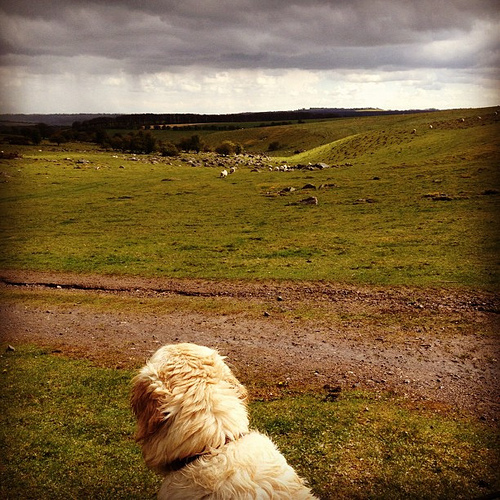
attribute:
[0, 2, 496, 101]
clouds — dark, grey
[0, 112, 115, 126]
tree line — grey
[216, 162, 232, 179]
animal — white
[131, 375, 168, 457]
ears — brown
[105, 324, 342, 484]
dog — blonde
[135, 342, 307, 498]
fur — brown, light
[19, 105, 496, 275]
hills — grassy, green, rolling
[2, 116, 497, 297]
rolling hills — green, grassy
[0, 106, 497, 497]
grass — soggy, green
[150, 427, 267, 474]
collar — black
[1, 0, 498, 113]
sky — grey, cloudy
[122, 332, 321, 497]
dog — tan, blonde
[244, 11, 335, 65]
sky — grey, cloudy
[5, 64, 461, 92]
clouds — white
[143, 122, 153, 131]
trees — green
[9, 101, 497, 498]
country side — hilly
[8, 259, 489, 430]
path — dirt, brown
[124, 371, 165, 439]
ear — brown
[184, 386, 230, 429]
fur — thick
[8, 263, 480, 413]
road — grey